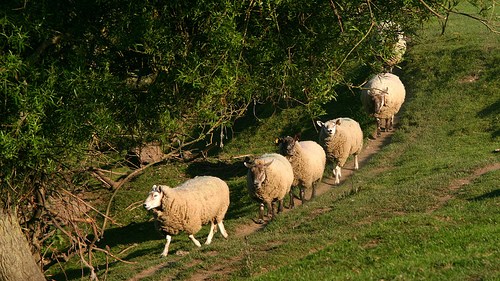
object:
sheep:
[275, 139, 324, 209]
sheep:
[315, 116, 360, 178]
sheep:
[358, 70, 405, 135]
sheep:
[246, 153, 307, 220]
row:
[110, 17, 421, 281]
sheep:
[134, 175, 232, 247]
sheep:
[363, 73, 407, 134]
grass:
[84, 7, 498, 279]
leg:
[158, 230, 173, 258]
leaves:
[184, 32, 286, 97]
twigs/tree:
[14, 170, 142, 281]